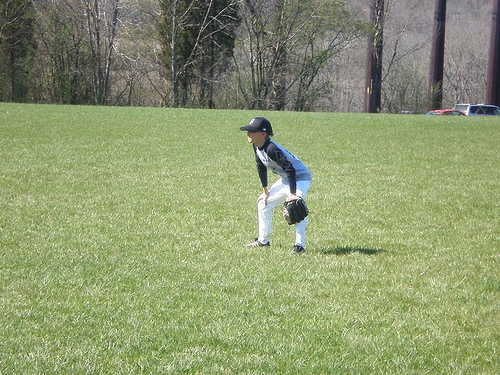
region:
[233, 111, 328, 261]
boy in baseball uniform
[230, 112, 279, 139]
hat of boy playing baseball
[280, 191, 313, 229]
baseball mitt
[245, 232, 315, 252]
cleats of boy playing baseball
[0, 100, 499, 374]
grassy area boy is standing on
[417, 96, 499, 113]
cars parked in the background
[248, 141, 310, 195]
long sleeve baseball shirt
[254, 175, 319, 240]
white baseball pants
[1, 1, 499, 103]
line of trees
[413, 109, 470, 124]
red car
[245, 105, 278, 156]
Person wearing black hat.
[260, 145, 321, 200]
Black sleeves on shirt.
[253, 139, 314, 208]
Boy wearing black and gray shirt.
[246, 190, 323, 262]
Boy wearing white pants.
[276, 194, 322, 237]
Black mitt on boy's left hand.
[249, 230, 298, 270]
Boy wearing white socks.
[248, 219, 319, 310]
Boy wearing black shoes.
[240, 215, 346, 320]
Boy standing in grassy field.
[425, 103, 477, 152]
Red car parked in distance.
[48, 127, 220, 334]
Grass is green in field.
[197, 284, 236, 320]
Small patch of green grass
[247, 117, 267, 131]
Dark blue cap of little kid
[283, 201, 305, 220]
Catching mitt of little kid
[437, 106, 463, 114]
Top of red car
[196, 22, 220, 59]
Few branches on the tree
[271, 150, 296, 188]
Black long sleeves of kid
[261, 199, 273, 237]
White pants of the boy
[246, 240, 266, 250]
Right black shoe of the kid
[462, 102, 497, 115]
Top section of the white mini van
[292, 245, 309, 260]
Left black shoe of kid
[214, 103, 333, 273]
a baseball player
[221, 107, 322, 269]
a kid in white pants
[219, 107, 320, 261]
a kid with a baseball glove on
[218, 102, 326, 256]
a kid wearing a baseball cap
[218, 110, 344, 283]
a kid wearing a long sleeve shirt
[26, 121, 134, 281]
a grassy field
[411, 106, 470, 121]
a top of a red car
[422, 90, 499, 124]
vehicles in the background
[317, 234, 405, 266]
a shadow of a kid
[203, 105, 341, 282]
a baseball player ready to play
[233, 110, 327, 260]
boy crouched in field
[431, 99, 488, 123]
roofs of distant cars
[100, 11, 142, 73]
tree with no leaves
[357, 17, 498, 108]
three poles in distance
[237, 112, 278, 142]
cap on boy's head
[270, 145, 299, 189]
black sleeves of shirt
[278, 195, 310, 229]
baseball glove on hand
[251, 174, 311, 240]
white pants on legs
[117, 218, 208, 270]
green grass on ground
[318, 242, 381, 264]
shadow of boy on grass